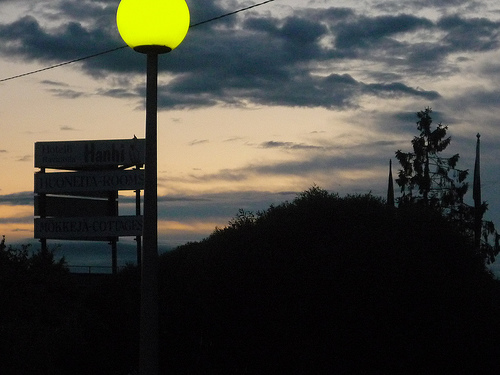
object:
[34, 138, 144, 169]
sign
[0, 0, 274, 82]
cable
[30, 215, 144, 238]
sign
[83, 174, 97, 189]
letter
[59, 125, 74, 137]
cloud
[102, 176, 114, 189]
letter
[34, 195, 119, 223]
sign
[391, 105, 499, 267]
tree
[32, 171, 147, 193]
sign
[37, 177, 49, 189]
letter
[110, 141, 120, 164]
black letter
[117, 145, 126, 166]
letter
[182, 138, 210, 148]
clouds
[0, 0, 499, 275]
sky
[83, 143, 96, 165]
letter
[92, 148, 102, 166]
letter